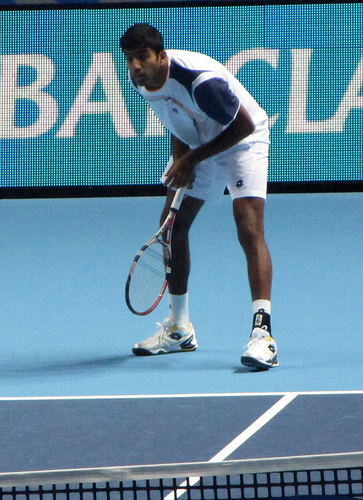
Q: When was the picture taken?
A: Daytime.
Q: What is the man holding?
A: Tennis racket.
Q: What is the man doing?
A: Bending.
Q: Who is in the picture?
A: A man.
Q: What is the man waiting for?
A: The ball.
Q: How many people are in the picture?
A: One.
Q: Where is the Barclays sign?
A: Background.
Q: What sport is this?
A: Tennis.